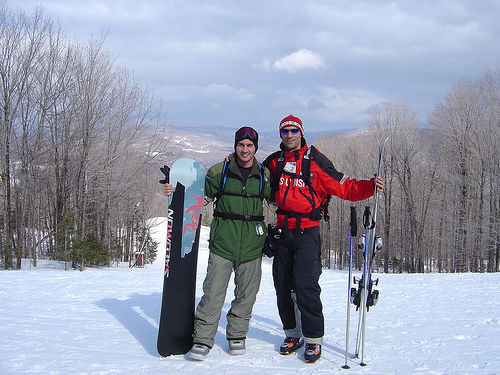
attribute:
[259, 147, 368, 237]
ski jacket — red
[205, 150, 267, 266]
ski jacket — green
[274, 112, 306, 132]
hat — red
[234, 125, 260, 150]
hat — black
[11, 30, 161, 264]
trees — barren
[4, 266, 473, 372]
snow — bright white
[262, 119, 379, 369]
man — white, red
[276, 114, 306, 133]
cap — red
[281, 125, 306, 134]
sunglasses — blue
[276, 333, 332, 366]
ski boots — black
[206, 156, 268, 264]
jacket — green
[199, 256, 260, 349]
trousers — gray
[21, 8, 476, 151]
clouds — white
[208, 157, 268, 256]
jacket — green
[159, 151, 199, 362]
snowboard — gray, black, red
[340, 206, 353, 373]
pole — ski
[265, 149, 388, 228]
jacket — red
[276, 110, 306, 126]
cap — red, wool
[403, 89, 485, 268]
trees — bare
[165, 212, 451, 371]
trail — snow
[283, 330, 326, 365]
boots — black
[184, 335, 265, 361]
boots — gray, white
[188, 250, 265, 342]
pants — gray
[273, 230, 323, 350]
pants — gray, blue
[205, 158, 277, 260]
jacket — green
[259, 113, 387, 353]
man — white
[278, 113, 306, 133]
hat — red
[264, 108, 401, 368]
man — black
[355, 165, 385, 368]
skis — silver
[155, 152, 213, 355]
snowboard — blue, black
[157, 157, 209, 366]
snowboard — black, blue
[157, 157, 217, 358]
snowboard — blue, black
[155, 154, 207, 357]
snowboard — blue, black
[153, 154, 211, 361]
snowboard — black, blue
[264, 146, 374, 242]
coat — red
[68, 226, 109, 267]
bush — small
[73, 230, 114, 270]
leaves — green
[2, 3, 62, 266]
tree — tall, leafless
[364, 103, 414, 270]
tree — leafless, tall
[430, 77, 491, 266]
tree — tall, leafless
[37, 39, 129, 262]
tree — leafless, tall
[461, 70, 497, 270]
tree — tall, leafless